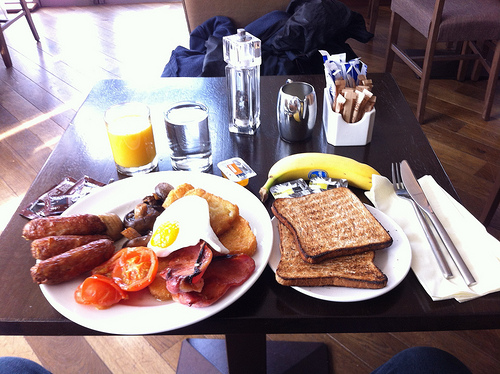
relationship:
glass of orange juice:
[105, 102, 159, 175] [106, 118, 158, 168]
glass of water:
[163, 102, 213, 172] [166, 105, 213, 161]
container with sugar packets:
[322, 86, 375, 147] [334, 74, 377, 123]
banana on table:
[258, 152, 381, 204] [1, 72, 500, 373]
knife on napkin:
[401, 159, 478, 289] [364, 173, 499, 303]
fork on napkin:
[391, 162, 455, 281] [364, 173, 499, 303]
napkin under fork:
[364, 173, 499, 303] [391, 162, 455, 281]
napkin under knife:
[364, 173, 499, 303] [401, 159, 478, 289]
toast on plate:
[271, 186, 393, 263] [268, 202, 413, 303]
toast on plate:
[276, 221, 389, 289] [268, 202, 413, 303]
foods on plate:
[22, 182, 258, 310] [36, 170, 274, 336]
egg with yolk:
[148, 195, 230, 259] [150, 221, 178, 249]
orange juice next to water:
[106, 118, 158, 168] [166, 105, 213, 161]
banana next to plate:
[258, 152, 381, 204] [268, 202, 413, 303]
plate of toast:
[268, 202, 413, 303] [271, 186, 393, 263]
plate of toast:
[268, 202, 413, 303] [276, 221, 389, 289]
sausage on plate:
[23, 215, 108, 240] [36, 170, 274, 336]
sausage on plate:
[32, 234, 109, 259] [36, 170, 274, 336]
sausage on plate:
[31, 238, 115, 284] [36, 170, 274, 336]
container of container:
[217, 156, 258, 187] [217, 156, 258, 187]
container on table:
[217, 156, 258, 187] [1, 72, 500, 373]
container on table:
[322, 86, 375, 147] [1, 72, 500, 373]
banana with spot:
[258, 152, 381, 204] [267, 174, 273, 179]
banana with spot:
[258, 152, 381, 204] [368, 179, 373, 186]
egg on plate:
[148, 195, 230, 259] [36, 170, 274, 336]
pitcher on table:
[276, 79, 318, 146] [1, 72, 500, 373]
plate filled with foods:
[268, 202, 413, 303] [22, 182, 258, 310]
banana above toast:
[258, 152, 381, 204] [271, 186, 393, 263]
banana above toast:
[258, 152, 381, 204] [276, 221, 389, 289]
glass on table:
[163, 102, 213, 172] [1, 72, 500, 373]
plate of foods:
[268, 202, 413, 303] [22, 182, 258, 310]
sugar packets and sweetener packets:
[334, 74, 377, 123] [319, 49, 367, 83]